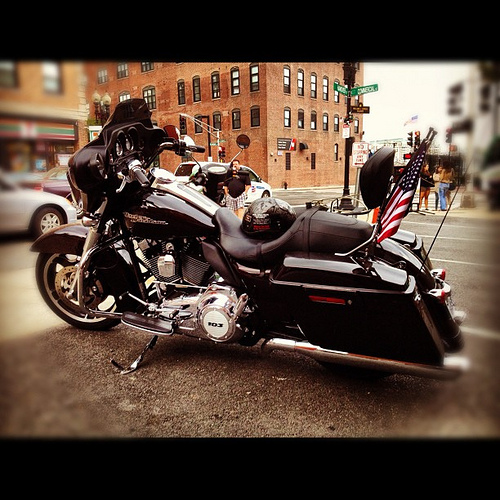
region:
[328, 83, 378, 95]
green street names on the street corner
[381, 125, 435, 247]
the U.S.flag on the back of a motorcycle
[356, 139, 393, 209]
the back cushion for a passenger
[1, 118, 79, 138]
a convenient store across the street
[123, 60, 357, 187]
large older red brick building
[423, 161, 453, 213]
people congregate on the corner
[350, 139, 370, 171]
a red and white No Parking sign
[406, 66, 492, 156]
a group of traffic lights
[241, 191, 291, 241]
a helmet resting in the seat of the motorcycle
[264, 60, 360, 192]
the facade of a building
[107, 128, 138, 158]
the speedometer and odometer of a motorcycle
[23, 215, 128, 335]
the front wheel of a motorcycle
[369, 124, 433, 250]
the American flag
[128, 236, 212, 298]
the engine of a motorcycle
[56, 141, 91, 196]
the headlight of a motorcycle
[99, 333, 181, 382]
the kickstand of a motorcycle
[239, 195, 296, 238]
a black motorcycle helmet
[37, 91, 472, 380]
Black two seater motorcycle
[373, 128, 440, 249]
American flag on a motorcycle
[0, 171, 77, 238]
White car driving on a road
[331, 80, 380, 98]
Two green street signs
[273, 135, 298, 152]
Brown and red sign on a building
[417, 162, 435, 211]
Woman wearing a black shirt and brown shorts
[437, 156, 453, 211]
Person wearing blue jeans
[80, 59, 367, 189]
Large brown brick building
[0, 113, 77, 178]
Storefront of a 711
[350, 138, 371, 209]
White sign on a pole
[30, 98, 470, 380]
A motorcycle is black with chrome on it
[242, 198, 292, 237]
A black helmet with red letters and white, and gold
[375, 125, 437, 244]
Two flags attached to the back of motorcycle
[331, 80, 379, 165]
There are street signs on the corner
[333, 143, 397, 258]
Back of the seat is a back rest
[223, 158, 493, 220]
People are standing on the corners and near Motorcycle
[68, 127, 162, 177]
Located in the middle of the handle bars is gauges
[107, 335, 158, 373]
The kick stand holds the motorcycle up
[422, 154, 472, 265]
At the back of motorcycle is an antenna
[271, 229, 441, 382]
Side compartments to store items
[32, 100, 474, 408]
Motorcycle parked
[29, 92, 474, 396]
Motorcycle is parked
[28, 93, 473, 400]
Black motorcycle parked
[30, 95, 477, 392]
Black motorcycle is parked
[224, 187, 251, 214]
Man wearing shorts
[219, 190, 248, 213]
Man is wearing shorts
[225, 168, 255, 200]
Man wearing a black shirt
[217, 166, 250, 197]
Man is wearing a black shirt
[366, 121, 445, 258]
American flag on the back of a motorcycle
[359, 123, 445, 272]
American flag is on the back of a motorcycle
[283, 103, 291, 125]
glass window on building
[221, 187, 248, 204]
hands in the pocket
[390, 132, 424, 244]
the flag is on the bike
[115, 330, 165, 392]
the kickstand is down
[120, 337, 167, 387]
the kickstand is metal